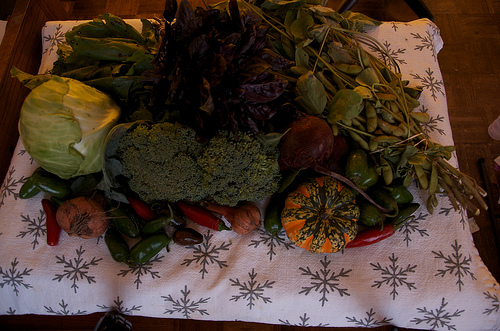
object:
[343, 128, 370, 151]
peppers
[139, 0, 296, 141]
lettuce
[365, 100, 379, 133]
green beans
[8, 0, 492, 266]
group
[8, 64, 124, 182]
vegetable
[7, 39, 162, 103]
vegetable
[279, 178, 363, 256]
vegetable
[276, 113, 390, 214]
vegetable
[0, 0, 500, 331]
ground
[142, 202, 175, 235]
peppers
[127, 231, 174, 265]
pepper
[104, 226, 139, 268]
green peppers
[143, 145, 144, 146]
heads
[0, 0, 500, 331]
flooring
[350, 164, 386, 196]
pepper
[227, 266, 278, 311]
snowflake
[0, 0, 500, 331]
table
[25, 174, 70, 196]
pepper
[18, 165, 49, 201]
pepper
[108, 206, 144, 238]
pepper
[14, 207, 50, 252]
snowflake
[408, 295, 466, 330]
snowflake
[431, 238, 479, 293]
snowflake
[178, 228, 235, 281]
snowflake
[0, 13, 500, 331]
fabric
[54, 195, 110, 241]
vegetables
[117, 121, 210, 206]
broccoli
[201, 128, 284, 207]
broccoli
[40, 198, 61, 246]
peppers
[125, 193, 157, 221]
peppers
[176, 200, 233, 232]
peppers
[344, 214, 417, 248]
peppers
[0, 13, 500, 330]
pillow